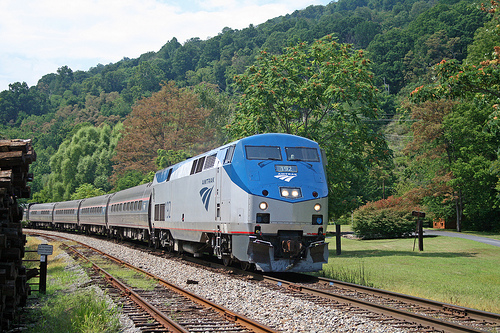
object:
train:
[21, 132, 332, 273]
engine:
[200, 242, 229, 259]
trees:
[302, 17, 438, 124]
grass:
[371, 249, 424, 292]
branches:
[290, 105, 321, 131]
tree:
[252, 41, 386, 129]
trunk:
[333, 224, 351, 258]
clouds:
[44, 1, 151, 43]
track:
[316, 280, 385, 308]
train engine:
[246, 229, 325, 270]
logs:
[0, 133, 39, 329]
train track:
[132, 279, 205, 322]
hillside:
[149, 2, 466, 114]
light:
[312, 203, 323, 212]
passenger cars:
[41, 190, 157, 229]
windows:
[55, 199, 147, 215]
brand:
[201, 177, 216, 185]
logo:
[198, 185, 215, 212]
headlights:
[279, 186, 303, 199]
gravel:
[184, 272, 211, 290]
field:
[444, 234, 498, 262]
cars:
[28, 202, 151, 225]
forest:
[79, 69, 179, 105]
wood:
[1, 214, 23, 273]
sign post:
[33, 243, 53, 264]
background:
[160, 36, 182, 58]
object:
[432, 215, 446, 229]